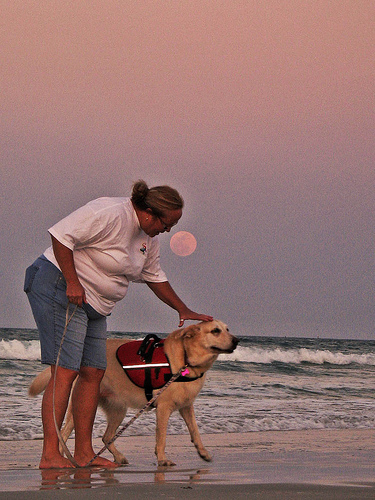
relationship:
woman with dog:
[61, 129, 172, 308] [153, 308, 258, 406]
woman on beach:
[61, 129, 172, 308] [28, 200, 373, 486]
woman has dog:
[61, 129, 172, 308] [153, 308, 258, 406]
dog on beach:
[153, 308, 258, 406] [28, 200, 373, 486]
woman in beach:
[61, 129, 172, 308] [28, 200, 373, 486]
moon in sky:
[171, 224, 208, 280] [30, 9, 333, 170]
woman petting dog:
[61, 129, 172, 308] [153, 308, 258, 406]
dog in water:
[153, 308, 258, 406] [266, 328, 329, 424]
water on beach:
[266, 328, 329, 424] [28, 200, 373, 486]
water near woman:
[266, 328, 329, 424] [61, 129, 172, 308]